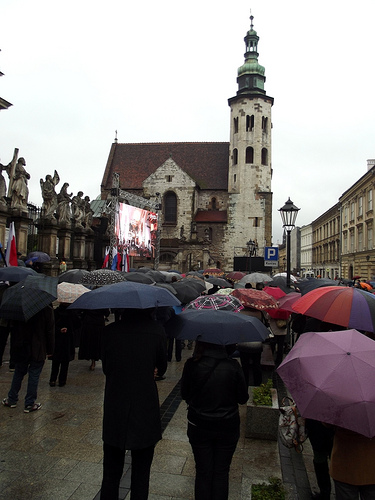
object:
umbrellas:
[276, 328, 375, 441]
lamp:
[278, 197, 301, 232]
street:
[290, 251, 373, 500]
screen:
[112, 198, 159, 260]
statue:
[4, 148, 32, 214]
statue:
[38, 171, 64, 278]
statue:
[57, 182, 73, 227]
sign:
[263, 246, 279, 267]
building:
[96, 7, 284, 273]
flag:
[5, 218, 19, 270]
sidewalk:
[0, 267, 248, 500]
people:
[94, 306, 168, 500]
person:
[176, 309, 264, 498]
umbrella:
[173, 307, 271, 355]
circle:
[343, 349, 355, 359]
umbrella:
[284, 283, 375, 329]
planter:
[246, 384, 280, 441]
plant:
[252, 379, 276, 408]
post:
[285, 231, 293, 291]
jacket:
[97, 309, 168, 449]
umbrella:
[262, 287, 288, 320]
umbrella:
[66, 281, 178, 312]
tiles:
[164, 411, 175, 417]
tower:
[222, 8, 277, 278]